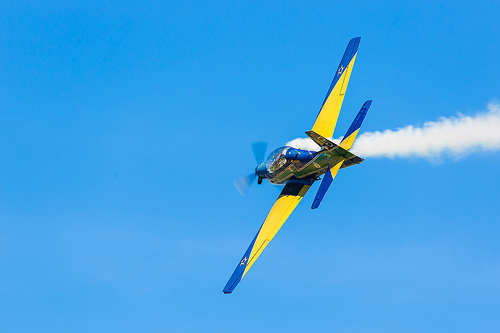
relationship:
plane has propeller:
[222, 36, 374, 294] [233, 140, 265, 194]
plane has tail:
[222, 36, 374, 294] [307, 132, 362, 165]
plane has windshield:
[222, 36, 374, 294] [263, 147, 287, 173]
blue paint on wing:
[319, 38, 360, 105] [311, 37, 364, 132]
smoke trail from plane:
[349, 114, 498, 166] [222, 36, 374, 294]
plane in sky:
[222, 36, 374, 294] [0, 4, 497, 332]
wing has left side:
[223, 185, 311, 293] [241, 183, 312, 265]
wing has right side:
[311, 37, 364, 132] [311, 78, 347, 136]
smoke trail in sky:
[349, 114, 498, 166] [0, 4, 497, 332]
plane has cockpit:
[222, 36, 374, 294] [264, 143, 312, 178]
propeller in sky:
[233, 140, 265, 194] [0, 4, 497, 332]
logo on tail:
[306, 132, 332, 153] [307, 132, 362, 165]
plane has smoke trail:
[222, 36, 374, 294] [349, 114, 498, 166]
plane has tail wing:
[222, 36, 374, 294] [339, 100, 372, 148]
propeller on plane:
[233, 140, 265, 194] [222, 36, 374, 294]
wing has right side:
[223, 185, 311, 293] [311, 78, 347, 136]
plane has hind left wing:
[222, 36, 374, 294] [312, 171, 343, 208]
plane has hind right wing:
[222, 36, 374, 294] [339, 100, 372, 148]